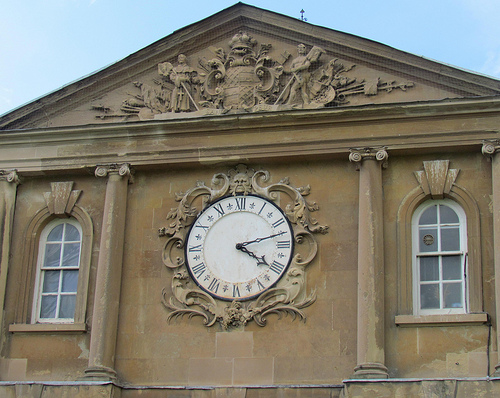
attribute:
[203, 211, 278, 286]
face — white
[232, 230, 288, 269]
hands — metal, black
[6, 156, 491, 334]
window — trimmed, framed, rounded, white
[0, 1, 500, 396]
building — limestone, designed, brick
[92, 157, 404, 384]
columns — carved, concrete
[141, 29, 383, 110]
sculpture — intricate, decorative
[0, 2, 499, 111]
sky — blue